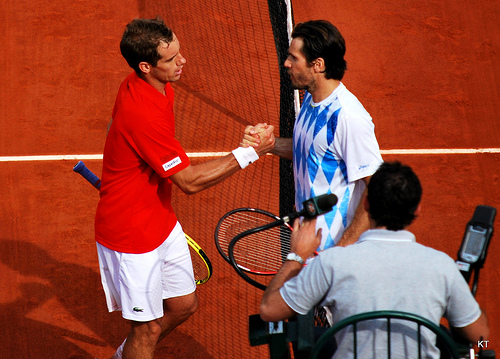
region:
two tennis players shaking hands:
[70, 13, 357, 264]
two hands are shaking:
[223, 114, 290, 169]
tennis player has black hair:
[98, 11, 224, 169]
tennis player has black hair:
[251, 10, 388, 162]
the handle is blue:
[67, 153, 102, 197]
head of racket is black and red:
[209, 200, 297, 282]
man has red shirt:
[83, 9, 283, 352]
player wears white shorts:
[85, 7, 280, 357]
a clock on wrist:
[274, 243, 313, 271]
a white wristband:
[230, 145, 261, 167]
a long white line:
[365, 138, 498, 161]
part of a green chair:
[306, 306, 459, 356]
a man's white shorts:
[88, 220, 199, 317]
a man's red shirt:
[85, 76, 190, 251]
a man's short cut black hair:
[289, 16, 351, 76]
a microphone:
[301, 191, 343, 216]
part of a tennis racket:
[211, 208, 293, 285]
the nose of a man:
[174, 50, 186, 65]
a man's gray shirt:
[280, 226, 483, 357]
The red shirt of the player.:
[100, 74, 181, 251]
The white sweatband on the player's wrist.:
[232, 143, 259, 168]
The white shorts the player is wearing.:
[99, 235, 197, 315]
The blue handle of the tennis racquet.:
[75, 160, 107, 189]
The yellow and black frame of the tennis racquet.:
[183, 232, 212, 288]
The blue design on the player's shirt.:
[299, 94, 350, 252]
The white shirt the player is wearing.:
[292, 95, 379, 245]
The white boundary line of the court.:
[3, 143, 498, 171]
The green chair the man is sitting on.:
[323, 310, 452, 356]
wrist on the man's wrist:
[232, 145, 257, 166]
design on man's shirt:
[153, 149, 186, 176]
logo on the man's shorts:
[124, 306, 147, 314]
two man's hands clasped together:
[238, 122, 280, 152]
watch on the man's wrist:
[283, 246, 307, 266]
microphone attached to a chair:
[306, 191, 342, 216]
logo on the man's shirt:
[352, 164, 374, 171]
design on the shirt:
[293, 102, 343, 187]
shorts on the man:
[96, 219, 193, 319]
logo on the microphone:
[308, 203, 313, 213]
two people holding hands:
[104, 0, 377, 243]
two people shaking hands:
[123, 3, 382, 158]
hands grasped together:
[233, 120, 278, 164]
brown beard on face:
[289, 69, 319, 84]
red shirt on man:
[87, 83, 190, 258]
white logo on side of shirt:
[153, 142, 189, 175]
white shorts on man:
[70, 221, 194, 331]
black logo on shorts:
[130, 300, 152, 315]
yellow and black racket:
[192, 234, 216, 297]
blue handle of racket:
[58, 158, 104, 194]